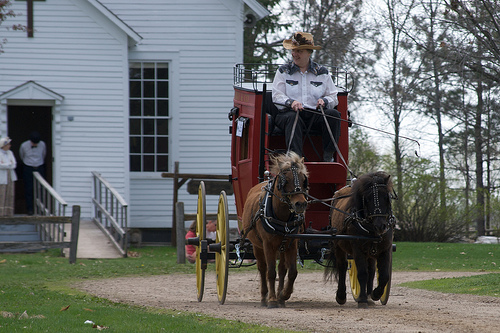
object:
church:
[2, 0, 269, 260]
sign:
[186, 179, 232, 196]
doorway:
[7, 104, 50, 213]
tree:
[444, 0, 493, 230]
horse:
[240, 150, 312, 308]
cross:
[0, 2, 67, 46]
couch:
[171, 62, 416, 317]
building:
[0, 0, 267, 256]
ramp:
[22, 189, 125, 246]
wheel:
[194, 180, 208, 300]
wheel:
[215, 186, 228, 306]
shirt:
[271, 62, 338, 109]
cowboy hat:
[279, 30, 325, 50]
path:
[78, 239, 497, 330]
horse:
[323, 171, 400, 311]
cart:
[186, 62, 397, 307]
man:
[270, 27, 343, 164]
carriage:
[185, 59, 398, 306]